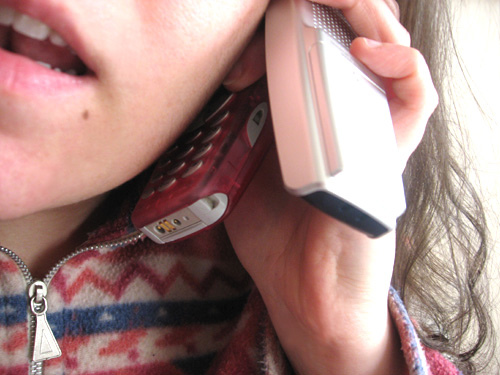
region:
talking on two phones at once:
[128, 0, 400, 242]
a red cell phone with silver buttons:
[131, 83, 271, 241]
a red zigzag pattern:
[52, 259, 239, 306]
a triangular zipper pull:
[11, 283, 65, 365]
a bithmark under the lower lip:
[80, 103, 95, 125]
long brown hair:
[387, 1, 498, 368]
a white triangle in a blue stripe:
[88, 303, 120, 328]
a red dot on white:
[124, 342, 144, 360]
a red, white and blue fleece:
[0, 233, 479, 373]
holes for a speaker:
[311, 1, 370, 50]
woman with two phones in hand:
[4, 0, 498, 372]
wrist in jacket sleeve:
[244, 297, 449, 373]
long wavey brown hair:
[406, 5, 493, 361]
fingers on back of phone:
[323, 0, 436, 135]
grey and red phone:
[133, 93, 270, 244]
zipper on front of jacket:
[0, 235, 137, 372]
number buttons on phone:
[146, 110, 223, 195]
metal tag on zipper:
[27, 281, 59, 362]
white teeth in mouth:
[1, 10, 59, 45]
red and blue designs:
[64, 260, 239, 333]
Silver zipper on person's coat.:
[28, 277, 67, 372]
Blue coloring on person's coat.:
[80, 294, 182, 326]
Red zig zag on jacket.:
[85, 260, 180, 292]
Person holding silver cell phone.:
[293, 73, 363, 155]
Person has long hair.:
[410, 258, 455, 320]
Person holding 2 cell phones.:
[193, 128, 415, 202]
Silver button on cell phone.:
[181, 159, 210, 179]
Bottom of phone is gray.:
[154, 211, 219, 239]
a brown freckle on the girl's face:
[80, 107, 90, 119]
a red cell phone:
[133, 76, 263, 241]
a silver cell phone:
[264, 3, 407, 238]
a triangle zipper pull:
[26, 286, 61, 363]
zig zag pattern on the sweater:
[45, 261, 245, 303]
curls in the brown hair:
[400, 153, 492, 364]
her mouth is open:
[0, 0, 97, 97]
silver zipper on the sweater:
[0, 235, 134, 373]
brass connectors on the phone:
[156, 218, 176, 233]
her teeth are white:
[0, 6, 64, 46]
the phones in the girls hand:
[120, 0, 431, 237]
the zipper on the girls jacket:
[17, 278, 59, 368]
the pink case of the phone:
[140, 100, 250, 256]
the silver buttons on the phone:
[149, 106, 227, 194]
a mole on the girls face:
[77, 105, 101, 132]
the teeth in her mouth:
[0, 3, 65, 55]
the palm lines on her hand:
[262, 199, 308, 296]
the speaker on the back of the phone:
[307, 3, 350, 45]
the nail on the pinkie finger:
[359, 33, 390, 53]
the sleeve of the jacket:
[382, 288, 424, 373]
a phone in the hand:
[220, 43, 398, 220]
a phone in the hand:
[283, 40, 407, 230]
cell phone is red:
[164, 88, 263, 248]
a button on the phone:
[184, 156, 206, 186]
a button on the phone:
[154, 177, 175, 197]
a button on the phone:
[137, 192, 158, 214]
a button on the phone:
[179, 130, 207, 165]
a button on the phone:
[194, 133, 219, 165]